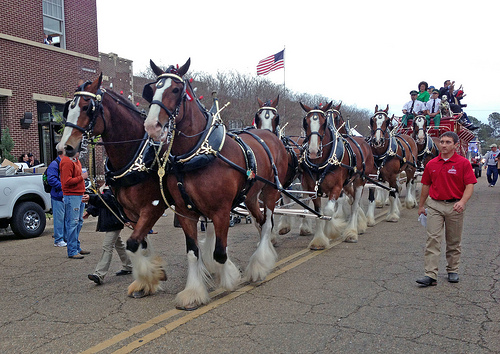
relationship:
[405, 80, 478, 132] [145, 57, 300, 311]
people carried by horse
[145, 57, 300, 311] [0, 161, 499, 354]
horse on floor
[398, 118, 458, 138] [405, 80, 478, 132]
carriage has people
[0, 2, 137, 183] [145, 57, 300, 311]
building behind horse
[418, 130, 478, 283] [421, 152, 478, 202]
man wearing shirt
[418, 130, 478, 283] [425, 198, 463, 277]
man wearing pants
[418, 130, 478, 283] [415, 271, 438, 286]
man wearing shoe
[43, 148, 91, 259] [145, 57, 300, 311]
people by horse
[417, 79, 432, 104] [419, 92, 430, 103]
woman wearing green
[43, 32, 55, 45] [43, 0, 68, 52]
person in window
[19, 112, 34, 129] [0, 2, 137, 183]
object on building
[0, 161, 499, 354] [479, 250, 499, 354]
floor has crack